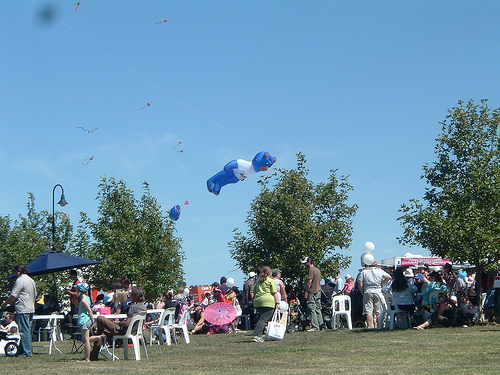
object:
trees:
[394, 97, 499, 296]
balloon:
[204, 150, 276, 196]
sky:
[0, 0, 499, 286]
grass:
[0, 324, 499, 375]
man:
[0, 264, 38, 361]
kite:
[74, 127, 99, 135]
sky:
[366, 32, 499, 105]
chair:
[111, 311, 150, 362]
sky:
[130, 0, 306, 99]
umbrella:
[7, 250, 99, 313]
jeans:
[14, 313, 35, 353]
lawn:
[323, 353, 392, 370]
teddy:
[205, 151, 278, 196]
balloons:
[361, 241, 375, 256]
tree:
[226, 149, 359, 297]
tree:
[226, 150, 361, 302]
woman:
[248, 265, 282, 343]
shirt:
[249, 276, 279, 309]